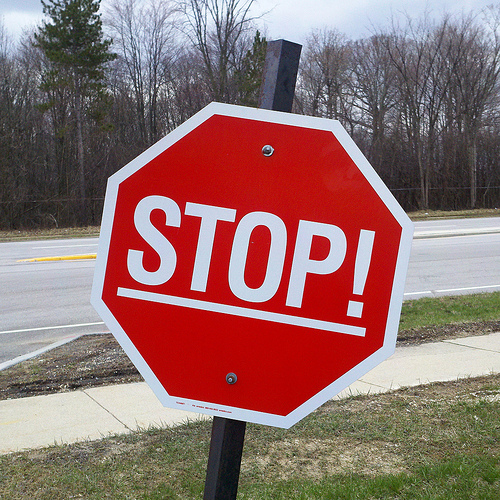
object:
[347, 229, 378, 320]
exclamation mark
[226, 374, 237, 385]
pin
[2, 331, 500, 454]
sidewalk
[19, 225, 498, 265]
line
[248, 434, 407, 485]
sand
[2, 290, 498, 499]
grass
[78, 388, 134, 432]
groove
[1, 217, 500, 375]
road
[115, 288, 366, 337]
line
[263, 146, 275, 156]
screw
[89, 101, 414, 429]
border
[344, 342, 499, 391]
section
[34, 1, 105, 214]
tree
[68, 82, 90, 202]
trunk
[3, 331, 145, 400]
dirt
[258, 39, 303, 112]
post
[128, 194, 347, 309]
lettering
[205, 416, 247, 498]
pole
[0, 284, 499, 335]
line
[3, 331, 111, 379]
curb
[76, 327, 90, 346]
point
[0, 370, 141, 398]
tracks